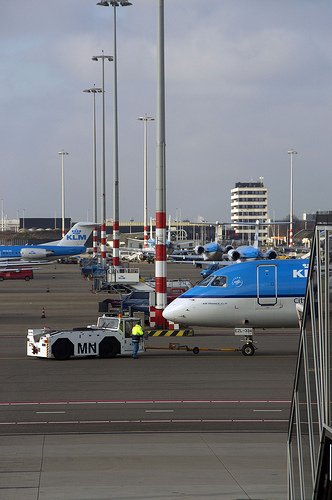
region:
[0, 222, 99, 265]
white and blue plane at an airport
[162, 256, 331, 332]
white and blue plane at an airport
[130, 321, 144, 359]
worker with a bright yellow coat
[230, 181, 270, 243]
white tower with glass windows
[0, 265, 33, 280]
red van at an airport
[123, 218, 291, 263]
several white and blue planes parked at airport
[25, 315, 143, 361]
white vehicle at airport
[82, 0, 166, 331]
tall metal light posts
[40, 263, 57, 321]
row of orange traffic cones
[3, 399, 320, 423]
lines on airport runway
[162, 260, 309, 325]
blue and white plane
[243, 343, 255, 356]
black tire on plane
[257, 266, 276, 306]
blue door on plane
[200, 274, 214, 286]
wind shield on plane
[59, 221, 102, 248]
white tail on plane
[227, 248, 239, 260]
booster jet on plane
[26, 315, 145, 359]
white truck on runway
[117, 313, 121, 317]
orange light on truck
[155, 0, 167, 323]
red white and grey pole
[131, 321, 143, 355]
man with yellow jacket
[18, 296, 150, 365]
white cart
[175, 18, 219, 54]
white clouds in blue sky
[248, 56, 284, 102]
white clouds in blue sky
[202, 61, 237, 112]
white clouds in blue sky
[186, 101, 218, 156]
white clouds in blue sky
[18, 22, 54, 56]
white clouds in blue sky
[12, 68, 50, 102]
white clouds in blue sky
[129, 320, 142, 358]
man wears bright jacket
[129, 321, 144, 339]
bright jacket is worn by man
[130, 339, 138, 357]
pants are worn by man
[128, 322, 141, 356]
man wears pants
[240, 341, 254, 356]
wheel is attached to plane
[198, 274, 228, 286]
window allows pilot to see from inside plane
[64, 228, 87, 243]
logo is printed on plane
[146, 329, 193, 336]
stripes are used to draw attention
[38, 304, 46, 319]
cone sits on tarmac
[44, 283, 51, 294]
cone sits on tarmac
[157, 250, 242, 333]
The nose of an airplane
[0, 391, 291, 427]
White and red lines on the tarmac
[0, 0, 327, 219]
The sky appears to be very cloudy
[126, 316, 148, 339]
Person wearing a bright yellow jacket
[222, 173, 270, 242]
A tall white building with windows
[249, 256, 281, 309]
A door on the plane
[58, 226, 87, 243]
"KLM" written in blue letters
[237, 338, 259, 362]
A black round wheel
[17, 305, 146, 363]
A white vehicle on the tarmac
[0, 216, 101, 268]
A white and blue airplane